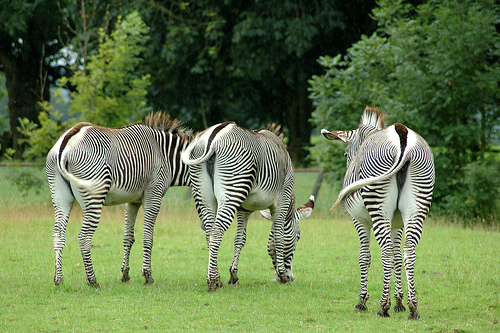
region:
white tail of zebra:
[330, 150, 413, 208]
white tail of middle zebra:
[176, 127, 233, 200]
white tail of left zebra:
[40, 130, 117, 210]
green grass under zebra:
[141, 280, 308, 330]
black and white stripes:
[203, 118, 305, 197]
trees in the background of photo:
[105, 40, 340, 132]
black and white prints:
[90, 125, 120, 175]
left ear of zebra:
[316, 125, 346, 155]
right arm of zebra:
[250, 200, 305, 275]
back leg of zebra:
[376, 260, 446, 315]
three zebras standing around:
[32, 108, 437, 323]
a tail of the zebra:
[53, 155, 93, 201]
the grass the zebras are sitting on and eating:
[8, 216, 495, 327]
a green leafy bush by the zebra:
[430, 125, 499, 222]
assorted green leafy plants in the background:
[13, 8, 499, 133]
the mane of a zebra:
[352, 105, 383, 132]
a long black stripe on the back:
[391, 120, 411, 152]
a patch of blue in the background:
[51, 87, 70, 117]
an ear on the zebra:
[294, 193, 314, 220]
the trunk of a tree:
[307, 165, 322, 209]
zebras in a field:
[35, 76, 476, 330]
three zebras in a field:
[49, 36, 464, 332]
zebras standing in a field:
[39, 50, 457, 330]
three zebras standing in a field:
[26, 45, 466, 298]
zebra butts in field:
[17, 54, 493, 330]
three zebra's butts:
[36, 44, 496, 331]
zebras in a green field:
[35, 40, 482, 318]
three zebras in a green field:
[22, 69, 482, 331]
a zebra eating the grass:
[35, 55, 499, 332]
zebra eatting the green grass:
[179, 81, 349, 332]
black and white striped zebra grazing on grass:
[24, 101, 194, 286]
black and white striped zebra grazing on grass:
[169, 114, 296, 272]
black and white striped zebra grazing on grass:
[310, 101, 467, 321]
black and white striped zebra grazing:
[32, 101, 183, 275]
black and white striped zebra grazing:
[180, 115, 307, 284]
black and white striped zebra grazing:
[320, 100, 452, 326]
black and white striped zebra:
[49, 103, 201, 279]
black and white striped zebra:
[187, 91, 308, 292]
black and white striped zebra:
[309, 92, 438, 320]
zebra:
[312, 96, 449, 322]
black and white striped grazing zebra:
[24, 101, 207, 272]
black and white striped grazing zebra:
[193, 92, 306, 297]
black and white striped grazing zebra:
[309, 101, 446, 325]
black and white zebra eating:
[33, 99, 205, 306]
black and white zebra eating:
[190, 117, 305, 291]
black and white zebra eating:
[320, 103, 434, 330]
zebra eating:
[178, 103, 310, 286]